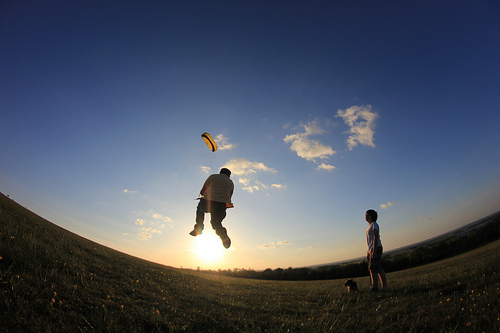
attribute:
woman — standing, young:
[368, 195, 385, 287]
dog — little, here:
[341, 280, 360, 292]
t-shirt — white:
[358, 222, 384, 244]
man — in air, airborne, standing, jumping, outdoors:
[194, 186, 242, 241]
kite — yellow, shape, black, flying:
[197, 128, 232, 148]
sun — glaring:
[195, 235, 225, 262]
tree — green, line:
[258, 250, 320, 277]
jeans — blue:
[178, 209, 232, 232]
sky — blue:
[24, 23, 88, 54]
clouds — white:
[280, 134, 345, 177]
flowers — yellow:
[35, 284, 104, 306]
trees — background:
[262, 269, 306, 281]